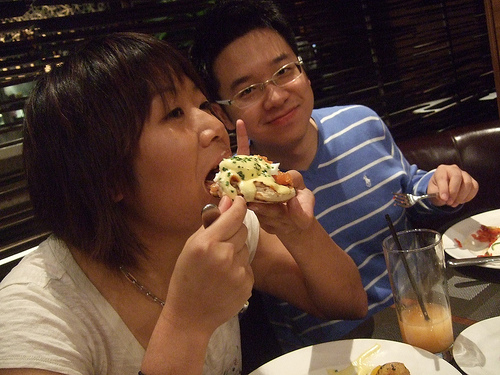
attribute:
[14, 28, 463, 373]
couple — asian, young, eating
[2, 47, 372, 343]
person — eating, wearing, asian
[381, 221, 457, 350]
glass — clear, cup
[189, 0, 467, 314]
man — asian, smiling, eating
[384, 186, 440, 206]
fork — silver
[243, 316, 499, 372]
plates — white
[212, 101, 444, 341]
shirt — striped, blue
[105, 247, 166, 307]
necklace — silver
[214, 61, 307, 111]
glasses — on, white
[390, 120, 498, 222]
booth — burgundy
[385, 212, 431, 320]
straw — black, glass, brown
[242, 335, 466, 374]
plate — white, large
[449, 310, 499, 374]
plate — white, small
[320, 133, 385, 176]
stripe — white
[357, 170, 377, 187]
logo — horse